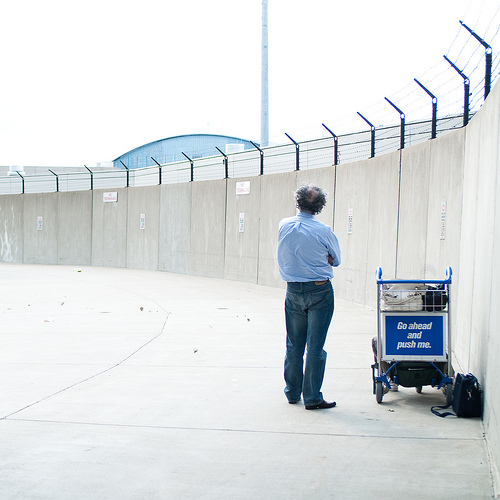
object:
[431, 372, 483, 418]
bag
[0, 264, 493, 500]
ground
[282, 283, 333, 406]
jeans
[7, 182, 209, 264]
wall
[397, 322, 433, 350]
words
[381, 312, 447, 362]
sign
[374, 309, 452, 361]
sign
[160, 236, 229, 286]
surface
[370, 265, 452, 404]
cart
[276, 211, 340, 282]
shirt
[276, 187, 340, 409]
man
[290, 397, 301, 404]
shoes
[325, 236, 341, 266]
arms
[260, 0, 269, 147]
pole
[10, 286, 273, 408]
plane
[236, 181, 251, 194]
sign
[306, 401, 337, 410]
black shoes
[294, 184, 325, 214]
hair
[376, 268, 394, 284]
metal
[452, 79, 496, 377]
wall